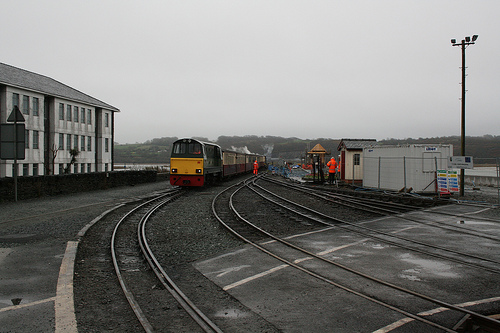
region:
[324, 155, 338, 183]
man in orange vest.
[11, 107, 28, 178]
sign to direct traffic.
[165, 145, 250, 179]
train on the tracks.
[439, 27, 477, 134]
tall pole with lights.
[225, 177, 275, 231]
railroad tracks on the ground.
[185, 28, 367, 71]
gray, overcast sky above.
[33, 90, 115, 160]
three story white building.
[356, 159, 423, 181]
fence to separate areas.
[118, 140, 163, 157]
hills in the background.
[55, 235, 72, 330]
painted lines on the ground.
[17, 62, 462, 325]
There are multiple tracks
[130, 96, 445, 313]
There is a track with a train on it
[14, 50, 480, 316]
The sky is gray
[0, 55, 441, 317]
There is a building in the background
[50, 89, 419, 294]
Front of the train is red and yellow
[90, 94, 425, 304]
There is only one train in the photo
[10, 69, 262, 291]
The building to the left has multiple windows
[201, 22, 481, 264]
There are persons wearing orange jackets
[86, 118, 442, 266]
There are trees in the background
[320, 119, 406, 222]
There is a small building next to the tracks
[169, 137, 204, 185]
front of a train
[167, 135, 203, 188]
a yellow train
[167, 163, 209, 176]
headlights on the front of a train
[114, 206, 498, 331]
4 sets of train tracks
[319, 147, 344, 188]
person in an orange top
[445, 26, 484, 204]
lights on a pole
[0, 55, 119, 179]
a multiple story building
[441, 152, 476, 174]
a sign on the fence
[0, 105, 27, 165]
the back side of a sign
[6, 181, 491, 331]
a crossing area for cars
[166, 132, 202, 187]
the black and yellow front of a train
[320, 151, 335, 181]
a person near the train tracks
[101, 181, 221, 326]
a pair of metal train tracks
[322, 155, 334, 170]
an orange coat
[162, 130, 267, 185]
a train on the train tracks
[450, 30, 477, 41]
a set of street lights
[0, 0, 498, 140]
a gray sky over the train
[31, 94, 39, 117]
a window on the building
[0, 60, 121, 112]
the roof of a building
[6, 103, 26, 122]
a triangular street sign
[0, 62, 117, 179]
three story building at edge of trainyard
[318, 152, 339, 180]
worker in orange standing out from black and white background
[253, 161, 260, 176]
worker in orange standing out from black and white backgroun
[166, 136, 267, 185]
train colored in red and yellow in a black and white photo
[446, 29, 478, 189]
tall pole with flood lights on top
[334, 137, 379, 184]
small shed on side of tracks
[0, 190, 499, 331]
trainyard with multiple sets of tracks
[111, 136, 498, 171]
trees in the distance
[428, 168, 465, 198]
signs attached to chianlink fence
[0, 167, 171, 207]
fence running between building and tracks